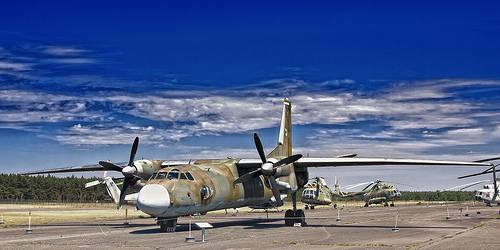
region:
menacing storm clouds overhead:
[121, 93, 237, 128]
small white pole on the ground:
[19, 205, 51, 235]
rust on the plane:
[177, 161, 222, 209]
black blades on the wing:
[224, 132, 313, 198]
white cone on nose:
[251, 160, 279, 182]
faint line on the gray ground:
[315, 225, 340, 247]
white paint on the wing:
[274, 92, 292, 154]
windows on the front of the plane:
[141, 164, 201, 179]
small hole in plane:
[187, 185, 198, 200]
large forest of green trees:
[18, 162, 104, 197]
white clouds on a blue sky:
[50, 77, 197, 147]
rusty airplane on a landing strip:
[21, 107, 484, 227]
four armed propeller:
[99, 131, 152, 209]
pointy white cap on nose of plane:
[131, 176, 171, 216]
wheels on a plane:
[282, 197, 314, 235]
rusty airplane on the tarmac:
[346, 172, 421, 208]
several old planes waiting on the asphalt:
[292, 133, 496, 229]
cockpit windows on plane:
[152, 166, 209, 187]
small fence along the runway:
[12, 192, 92, 207]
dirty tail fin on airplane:
[260, 90, 315, 165]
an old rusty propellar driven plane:
[20, 100, 492, 230]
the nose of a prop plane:
[135, 183, 172, 214]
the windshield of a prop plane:
[150, 169, 195, 182]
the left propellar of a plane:
[233, 133, 301, 203]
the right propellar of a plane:
[96, 138, 146, 207]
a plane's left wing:
[240, 155, 498, 168]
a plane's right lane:
[21, 160, 164, 175]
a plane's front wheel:
[155, 216, 180, 233]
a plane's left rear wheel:
[285, 207, 305, 224]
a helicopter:
[342, 180, 404, 204]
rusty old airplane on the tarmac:
[130, 140, 245, 221]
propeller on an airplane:
[91, 136, 161, 203]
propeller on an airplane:
[233, 129, 299, 216]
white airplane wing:
[301, 142, 492, 184]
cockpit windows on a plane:
[141, 165, 209, 192]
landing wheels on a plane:
[280, 202, 308, 228]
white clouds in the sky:
[140, 69, 215, 150]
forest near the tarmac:
[10, 171, 53, 202]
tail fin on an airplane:
[270, 86, 298, 156]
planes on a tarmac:
[34, 100, 476, 227]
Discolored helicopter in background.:
[341, 175, 426, 208]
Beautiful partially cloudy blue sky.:
[40, 35, 485, 99]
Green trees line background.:
[8, 171, 88, 203]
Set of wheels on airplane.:
[284, 210, 306, 225]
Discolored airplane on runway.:
[12, 97, 490, 231]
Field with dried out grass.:
[14, 206, 110, 221]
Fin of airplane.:
[265, 97, 298, 159]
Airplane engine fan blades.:
[233, 132, 300, 207]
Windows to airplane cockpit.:
[147, 171, 194, 182]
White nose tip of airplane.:
[135, 182, 170, 214]